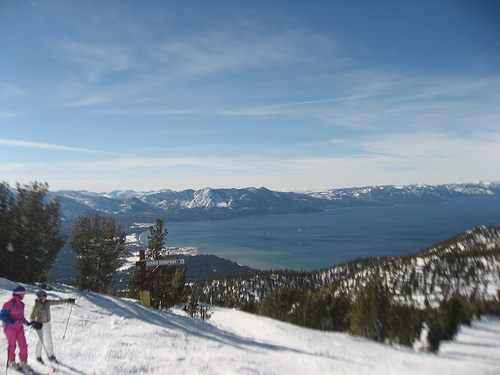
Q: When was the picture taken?
A: In Winter.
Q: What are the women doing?
A: Skiing.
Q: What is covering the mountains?
A: Snow.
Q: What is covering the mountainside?
A: Trees.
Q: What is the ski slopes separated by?
A: Trees.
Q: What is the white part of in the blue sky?
A: Clouds.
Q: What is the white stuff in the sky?
A: Clouds.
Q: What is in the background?
A: Mountains.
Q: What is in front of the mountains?
A: Water.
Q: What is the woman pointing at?
A: Snow.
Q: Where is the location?
A: Mountain.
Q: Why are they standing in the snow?
A: To ski.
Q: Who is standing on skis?
A: Two women.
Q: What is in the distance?
A: Snow capped mountains.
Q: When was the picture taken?
A: Daytime.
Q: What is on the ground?
A: Snow.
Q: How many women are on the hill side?
A: Two.